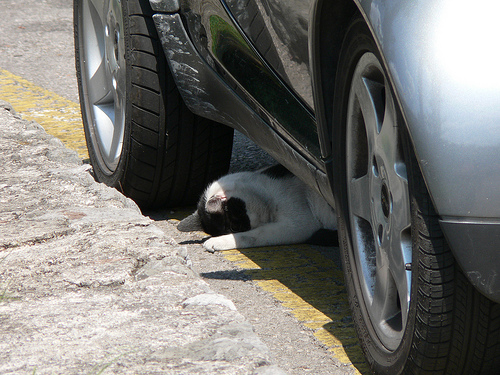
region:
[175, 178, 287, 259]
the head of a cat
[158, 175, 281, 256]
the ear of a cat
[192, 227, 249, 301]
the paw of a cat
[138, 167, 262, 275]
a black and white cat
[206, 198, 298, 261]
the leg of a cat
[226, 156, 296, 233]
the neck of a cat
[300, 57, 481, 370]
the tire on a car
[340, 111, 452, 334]
the rim on a car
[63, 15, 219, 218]
the back tire on a car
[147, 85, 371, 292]
a cat under a car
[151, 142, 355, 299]
the cat is under the car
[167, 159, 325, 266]
the cat is black and white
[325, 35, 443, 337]
the tires are black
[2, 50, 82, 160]
the line is yellow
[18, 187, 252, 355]
the curb is grey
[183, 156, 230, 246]
the sun is on the cats head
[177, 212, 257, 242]
the eye is closed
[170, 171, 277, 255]
the cats face is burried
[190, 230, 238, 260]
the paw is white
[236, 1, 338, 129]
the car is reflecting the seat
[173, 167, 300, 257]
A black and white cat covering its eyes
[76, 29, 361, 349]
A black and white cat napping under a car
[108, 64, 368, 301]
A black and white feline napping under a car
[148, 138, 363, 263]
A feline napping under a vehicle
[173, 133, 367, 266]
A cat napping under a gray car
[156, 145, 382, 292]
An adult cat napping under a vehicle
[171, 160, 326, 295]
An adult cat sleeping on a road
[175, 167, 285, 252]
An adult cat covering its eyes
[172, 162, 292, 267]
An adult black and white cat covering its eyes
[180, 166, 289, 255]
A black and white cat covering its eyes with a paw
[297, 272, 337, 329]
part of a shade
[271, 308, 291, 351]
part pof a road